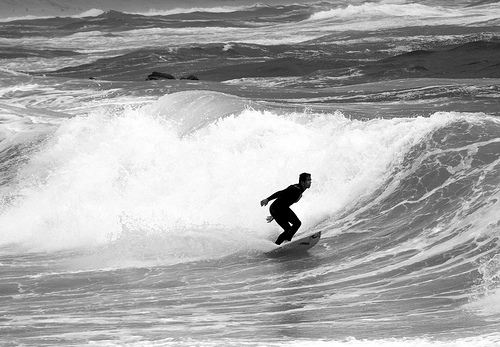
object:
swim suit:
[266, 184, 307, 245]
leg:
[275, 216, 293, 244]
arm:
[266, 185, 290, 200]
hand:
[260, 199, 268, 207]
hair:
[299, 172, 311, 183]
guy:
[260, 172, 312, 245]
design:
[300, 241, 309, 245]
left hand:
[266, 216, 274, 224]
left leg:
[286, 212, 302, 241]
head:
[298, 172, 312, 189]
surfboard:
[262, 231, 320, 258]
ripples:
[0, 7, 499, 162]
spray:
[0, 99, 469, 267]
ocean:
[0, 0, 499, 346]